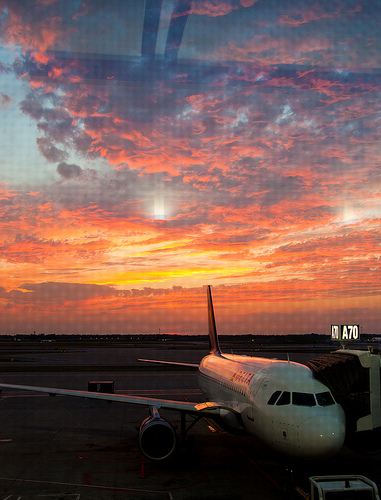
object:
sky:
[1, 2, 381, 332]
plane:
[3, 285, 347, 463]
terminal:
[304, 345, 380, 432]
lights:
[130, 333, 135, 341]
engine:
[137, 417, 178, 462]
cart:
[87, 380, 115, 395]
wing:
[1, 380, 241, 416]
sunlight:
[104, 241, 249, 288]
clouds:
[56, 161, 83, 183]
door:
[247, 369, 269, 423]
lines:
[4, 44, 139, 65]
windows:
[290, 388, 313, 408]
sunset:
[2, 230, 272, 319]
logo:
[229, 366, 253, 385]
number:
[348, 326, 358, 342]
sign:
[329, 322, 359, 340]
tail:
[204, 282, 220, 350]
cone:
[141, 457, 145, 476]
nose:
[302, 414, 349, 454]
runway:
[0, 348, 317, 395]